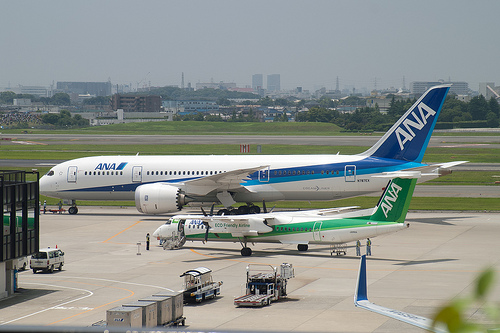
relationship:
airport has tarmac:
[1, 79, 491, 330] [0, 193, 495, 329]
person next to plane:
[352, 235, 364, 258] [139, 162, 452, 265]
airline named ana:
[153, 170, 426, 304] [373, 176, 415, 218]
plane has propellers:
[139, 162, 452, 265] [195, 196, 216, 245]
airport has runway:
[1, 79, 491, 330] [0, 108, 497, 170]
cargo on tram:
[101, 290, 193, 328] [173, 260, 224, 307]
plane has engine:
[16, 78, 458, 213] [126, 177, 195, 225]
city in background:
[1, 64, 492, 139] [0, 0, 492, 143]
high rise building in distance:
[251, 69, 264, 110] [0, 0, 492, 143]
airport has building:
[1, 79, 491, 330] [1, 149, 40, 309]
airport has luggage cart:
[1, 79, 491, 330] [227, 250, 300, 314]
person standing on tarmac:
[352, 235, 364, 258] [1, 79, 491, 330]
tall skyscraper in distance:
[267, 69, 287, 104] [0, 0, 492, 143]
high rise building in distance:
[250, 72, 264, 89] [0, 0, 492, 143]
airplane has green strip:
[139, 162, 452, 265] [163, 201, 405, 260]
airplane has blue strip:
[16, 78, 458, 213] [58, 151, 430, 189]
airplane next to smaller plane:
[16, 78, 458, 213] [139, 162, 452, 265]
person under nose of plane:
[39, 197, 50, 221] [26, 153, 68, 211]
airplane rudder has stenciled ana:
[383, 72, 455, 189] [375, 78, 453, 175]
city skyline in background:
[1, 64, 492, 139] [0, 0, 492, 143]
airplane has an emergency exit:
[139, 162, 452, 265] [305, 219, 334, 254]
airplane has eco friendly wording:
[139, 162, 452, 265] [202, 217, 257, 243]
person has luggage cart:
[53, 199, 62, 219] [25, 196, 72, 227]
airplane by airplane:
[163, 201, 405, 260] [16, 78, 458, 213]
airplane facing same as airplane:
[139, 162, 452, 265] [16, 78, 458, 213]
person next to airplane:
[352, 235, 364, 258] [163, 201, 405, 260]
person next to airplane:
[39, 197, 50, 221] [16, 78, 458, 213]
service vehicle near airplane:
[227, 250, 300, 314] [163, 201, 405, 260]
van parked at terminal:
[27, 237, 71, 285] [4, 120, 75, 332]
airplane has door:
[163, 201, 405, 260] [175, 217, 194, 245]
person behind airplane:
[352, 235, 364, 258] [139, 162, 452, 265]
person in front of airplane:
[142, 230, 159, 258] [139, 162, 452, 265]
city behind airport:
[1, 64, 492, 139] [1, 79, 491, 330]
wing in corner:
[351, 264, 432, 325] [372, 272, 473, 331]